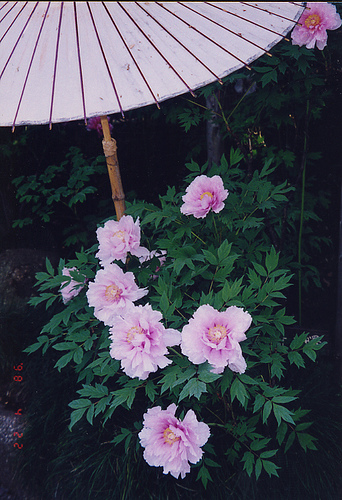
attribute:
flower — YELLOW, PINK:
[130, 246, 166, 273]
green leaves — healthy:
[239, 370, 322, 468]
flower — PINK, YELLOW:
[287, 0, 340, 51]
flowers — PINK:
[60, 175, 251, 480]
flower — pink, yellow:
[183, 305, 250, 369]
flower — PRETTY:
[180, 165, 239, 216]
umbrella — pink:
[2, 360, 29, 446]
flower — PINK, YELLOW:
[178, 172, 230, 220]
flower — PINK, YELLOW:
[94, 211, 144, 267]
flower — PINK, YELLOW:
[84, 262, 149, 323]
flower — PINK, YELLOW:
[180, 301, 254, 375]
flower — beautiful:
[137, 403, 210, 478]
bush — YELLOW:
[49, 253, 317, 472]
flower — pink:
[179, 180, 225, 220]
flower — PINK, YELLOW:
[290, 3, 341, 46]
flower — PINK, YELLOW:
[94, 211, 157, 266]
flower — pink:
[143, 403, 208, 482]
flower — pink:
[124, 408, 217, 477]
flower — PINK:
[135, 399, 211, 481]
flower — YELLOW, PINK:
[173, 297, 250, 375]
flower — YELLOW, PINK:
[107, 298, 181, 378]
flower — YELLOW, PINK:
[90, 214, 152, 265]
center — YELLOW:
[161, 427, 179, 444]